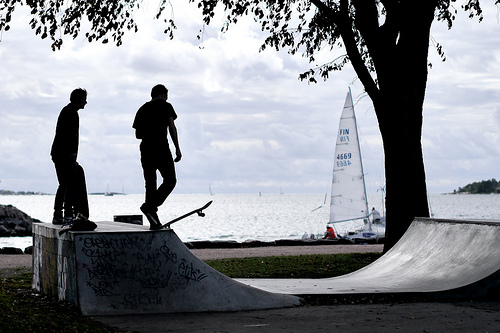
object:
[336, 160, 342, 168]
numbers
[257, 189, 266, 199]
boats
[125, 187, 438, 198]
horizon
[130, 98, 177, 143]
shirt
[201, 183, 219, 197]
sailboat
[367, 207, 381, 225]
person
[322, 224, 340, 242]
person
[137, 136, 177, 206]
pants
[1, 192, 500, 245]
water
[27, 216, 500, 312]
halfpipe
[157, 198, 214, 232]
skateboard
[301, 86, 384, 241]
boat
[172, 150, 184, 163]
left hand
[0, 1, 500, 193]
sky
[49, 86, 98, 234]
guy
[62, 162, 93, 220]
skateboard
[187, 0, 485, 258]
tree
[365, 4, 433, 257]
trunk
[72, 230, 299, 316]
side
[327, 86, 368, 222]
sail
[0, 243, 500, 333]
ground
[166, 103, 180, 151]
arm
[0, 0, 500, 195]
cloud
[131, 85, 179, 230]
guy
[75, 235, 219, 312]
graffiti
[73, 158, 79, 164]
hand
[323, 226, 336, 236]
orange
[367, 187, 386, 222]
sailboat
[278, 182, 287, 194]
sailboat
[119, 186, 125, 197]
sailboat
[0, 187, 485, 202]
distance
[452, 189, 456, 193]
tree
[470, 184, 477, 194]
tree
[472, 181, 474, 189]
tree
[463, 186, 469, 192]
tree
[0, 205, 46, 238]
pile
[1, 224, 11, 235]
rock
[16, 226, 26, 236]
rock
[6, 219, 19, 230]
rock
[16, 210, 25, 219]
rock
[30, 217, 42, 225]
rock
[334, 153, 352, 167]
writing